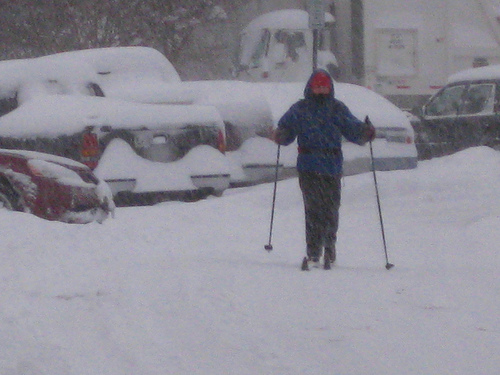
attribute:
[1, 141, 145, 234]
sedan — red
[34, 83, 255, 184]
truck — black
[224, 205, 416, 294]
skiis — cross country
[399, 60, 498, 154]
sedan — small, black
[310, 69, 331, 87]
cap — red, ski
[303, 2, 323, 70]
sign — white, green, street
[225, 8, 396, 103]
truck — white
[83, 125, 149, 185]
light — red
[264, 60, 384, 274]
skier — blue, red